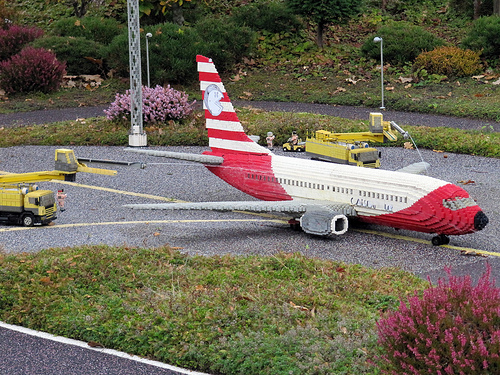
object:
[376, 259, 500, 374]
bush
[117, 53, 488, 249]
airplane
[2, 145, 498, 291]
pavement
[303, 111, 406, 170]
truck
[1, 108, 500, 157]
grass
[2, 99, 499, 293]
concrete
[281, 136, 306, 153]
jeep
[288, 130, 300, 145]
person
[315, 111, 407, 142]
lift apparatus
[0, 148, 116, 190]
lift apparatus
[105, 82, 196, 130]
bush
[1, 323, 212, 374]
line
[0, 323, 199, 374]
asphalt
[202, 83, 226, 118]
graphic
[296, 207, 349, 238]
engine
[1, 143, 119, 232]
toys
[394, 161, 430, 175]
wings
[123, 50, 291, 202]
back of plane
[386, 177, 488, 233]
front of plane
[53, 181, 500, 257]
lines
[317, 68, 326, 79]
plant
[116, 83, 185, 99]
top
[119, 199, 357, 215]
wing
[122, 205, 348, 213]
edge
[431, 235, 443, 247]
front wheel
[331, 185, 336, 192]
windows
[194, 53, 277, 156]
tail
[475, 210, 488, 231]
tip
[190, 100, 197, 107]
pink flowers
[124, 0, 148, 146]
pole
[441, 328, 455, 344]
flowers